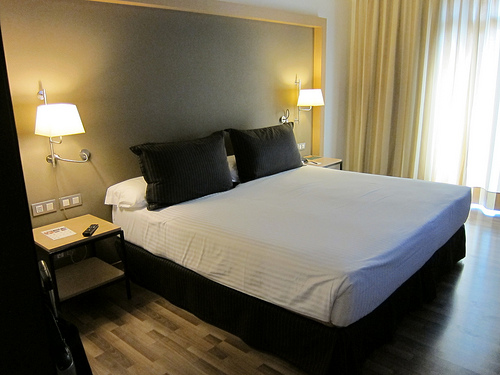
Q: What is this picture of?
A: A hotel room.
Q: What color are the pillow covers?
A: Black.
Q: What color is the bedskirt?
A: Black.